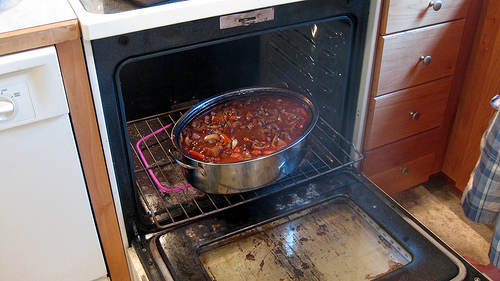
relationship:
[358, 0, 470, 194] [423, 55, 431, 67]
cabinet has a knob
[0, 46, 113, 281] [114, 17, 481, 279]
dishwasher next to oven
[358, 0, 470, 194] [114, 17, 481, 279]
cabinet next to oven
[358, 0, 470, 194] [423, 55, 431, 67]
cabinet has knob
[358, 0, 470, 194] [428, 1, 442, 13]
cabinet has knob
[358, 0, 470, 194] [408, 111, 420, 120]
cabinet has knob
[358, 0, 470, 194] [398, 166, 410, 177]
cabinet has knob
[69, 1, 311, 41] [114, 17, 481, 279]
top of oven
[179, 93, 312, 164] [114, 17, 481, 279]
stew in oven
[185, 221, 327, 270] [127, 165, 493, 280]
food on oven door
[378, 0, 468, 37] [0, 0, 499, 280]
drawer in kitchen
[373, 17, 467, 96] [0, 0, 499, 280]
drawer in kitchen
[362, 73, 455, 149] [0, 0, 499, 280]
drawer in kitchen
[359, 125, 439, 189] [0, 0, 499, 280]
drawer in kitchen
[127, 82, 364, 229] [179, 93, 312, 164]
grate holding stew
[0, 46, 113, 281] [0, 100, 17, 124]
dishwasher has knob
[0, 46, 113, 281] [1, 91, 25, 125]
dishwasher has wash cycles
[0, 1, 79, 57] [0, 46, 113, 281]
counter top above dishwasher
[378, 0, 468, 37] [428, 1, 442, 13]
drawer has knob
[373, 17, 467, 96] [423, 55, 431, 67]
drawer has knob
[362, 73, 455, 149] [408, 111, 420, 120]
drawer has knob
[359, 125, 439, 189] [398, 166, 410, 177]
drawer has knob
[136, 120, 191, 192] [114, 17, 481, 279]
heated wire in oven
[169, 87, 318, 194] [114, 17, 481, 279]
pot in oven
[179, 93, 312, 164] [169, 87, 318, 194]
stew in pot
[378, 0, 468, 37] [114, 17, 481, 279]
drawer next to oven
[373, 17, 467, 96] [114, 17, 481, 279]
drawer next to oven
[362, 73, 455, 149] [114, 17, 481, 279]
drawer next to oven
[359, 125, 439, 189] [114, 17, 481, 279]
drawer next to oven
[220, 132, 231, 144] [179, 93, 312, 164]
carrot in stew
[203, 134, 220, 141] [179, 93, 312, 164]
mushroom in stew